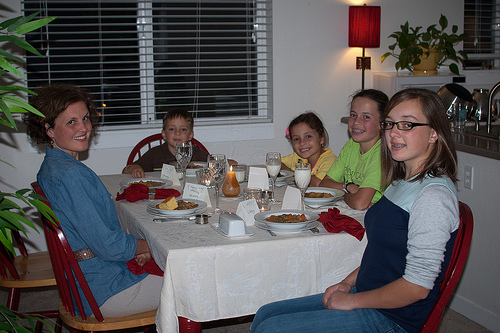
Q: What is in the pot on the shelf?
A: Plant.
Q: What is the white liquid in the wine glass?
A: Milk.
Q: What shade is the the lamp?
A: Red.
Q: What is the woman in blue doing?
A: Smiling.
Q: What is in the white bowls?
A: Food.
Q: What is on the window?
A: Shades.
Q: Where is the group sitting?
A: At a table.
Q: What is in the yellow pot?
A: A plant.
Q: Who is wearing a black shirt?
A: A boy.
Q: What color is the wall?
A: White.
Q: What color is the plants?
A: Green.